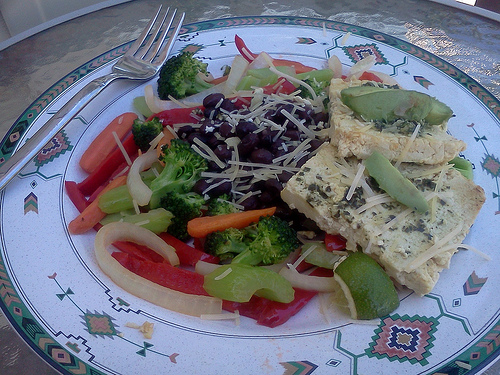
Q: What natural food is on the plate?
A: Vegetables.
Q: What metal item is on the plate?
A: A fork.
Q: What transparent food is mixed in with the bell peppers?
A: Onion.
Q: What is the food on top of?
A: A plate.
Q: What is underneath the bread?
A: A salad.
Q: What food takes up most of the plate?
A: A salad.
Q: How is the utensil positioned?
A: On the edge of the plate.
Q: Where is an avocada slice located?
A: On top of the white meat.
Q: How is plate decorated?
A: Geometric patterns on white.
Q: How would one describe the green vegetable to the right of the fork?
A: Broccoli.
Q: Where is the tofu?
A: Right side of plate.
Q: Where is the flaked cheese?
A: On top of the salad.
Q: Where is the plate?
A: On top of the place mat.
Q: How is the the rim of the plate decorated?
A: Gold trim.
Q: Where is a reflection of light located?
A: On place mat upper right.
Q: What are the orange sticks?
A: Carrots.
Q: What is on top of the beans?
A: Cheese.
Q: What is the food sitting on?
A: Plate.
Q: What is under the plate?
A: Glass table.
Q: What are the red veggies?
A: Red peppers.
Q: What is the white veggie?
A: Onion.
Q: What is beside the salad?
A: Fork.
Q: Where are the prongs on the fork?
A: At the top of the fork.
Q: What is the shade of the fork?
A: Silver.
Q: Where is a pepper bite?
A: On the left.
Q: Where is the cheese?
A: In the middle.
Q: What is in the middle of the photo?
A: Plate of food.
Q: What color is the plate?
A: White.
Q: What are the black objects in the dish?
A: Olives.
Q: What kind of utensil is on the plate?
A: Fork.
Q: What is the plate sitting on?
A: Table.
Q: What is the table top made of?
A: Glass.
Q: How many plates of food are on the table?
A: One.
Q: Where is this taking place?
A: On a table.